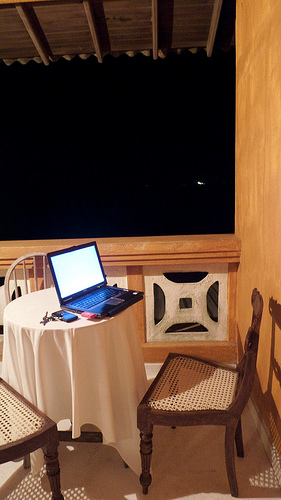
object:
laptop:
[46, 241, 143, 318]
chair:
[137, 287, 264, 498]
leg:
[225, 427, 236, 498]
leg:
[237, 433, 247, 464]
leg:
[137, 384, 149, 496]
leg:
[44, 440, 62, 495]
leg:
[26, 461, 34, 471]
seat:
[146, 355, 238, 414]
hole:
[151, 397, 159, 409]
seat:
[1, 387, 41, 436]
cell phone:
[51, 308, 78, 324]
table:
[19, 299, 34, 324]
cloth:
[22, 339, 118, 402]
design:
[141, 270, 227, 340]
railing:
[110, 240, 242, 261]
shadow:
[82, 459, 114, 494]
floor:
[165, 451, 220, 499]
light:
[196, 176, 201, 188]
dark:
[47, 87, 129, 124]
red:
[115, 14, 127, 26]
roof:
[6, 7, 222, 57]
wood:
[250, 321, 254, 344]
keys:
[39, 311, 49, 326]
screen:
[69, 268, 82, 273]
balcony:
[0, 47, 234, 242]